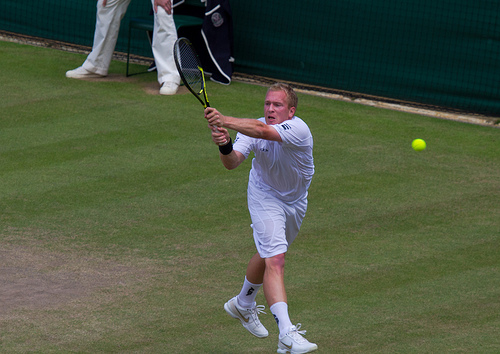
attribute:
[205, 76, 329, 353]
man — playing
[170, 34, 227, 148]
racket — black, yellow, green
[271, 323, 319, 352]
shoes — white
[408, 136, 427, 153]
ball — in air, green, round, in midair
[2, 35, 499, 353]
court — green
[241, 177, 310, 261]
shorts — white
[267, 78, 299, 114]
hair — blonde, short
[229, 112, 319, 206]
shirt — white